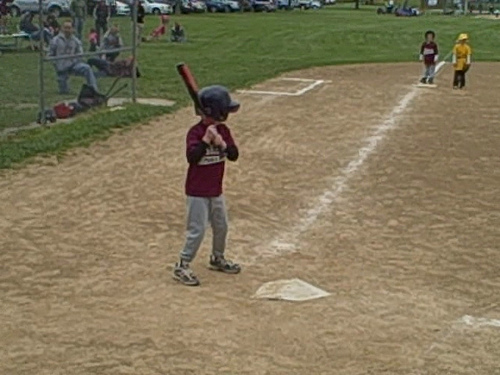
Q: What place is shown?
A: It is a field.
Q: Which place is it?
A: It is a field.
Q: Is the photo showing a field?
A: Yes, it is showing a field.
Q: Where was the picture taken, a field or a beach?
A: It was taken at a field.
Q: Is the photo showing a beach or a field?
A: It is showing a field.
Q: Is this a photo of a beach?
A: No, the picture is showing a field.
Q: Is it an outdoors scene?
A: Yes, it is outdoors.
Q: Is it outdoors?
A: Yes, it is outdoors.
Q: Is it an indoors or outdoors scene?
A: It is outdoors.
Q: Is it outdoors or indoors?
A: It is outdoors.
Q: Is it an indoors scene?
A: No, it is outdoors.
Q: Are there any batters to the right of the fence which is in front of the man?
A: Yes, there is a batter to the right of the fence.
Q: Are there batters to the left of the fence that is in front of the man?
A: No, the batter is to the right of the fence.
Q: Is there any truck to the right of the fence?
A: No, there is a batter to the right of the fence.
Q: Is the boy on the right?
A: Yes, the boy is on the right of the image.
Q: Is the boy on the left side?
A: No, the boy is on the right of the image.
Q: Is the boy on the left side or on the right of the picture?
A: The boy is on the right of the image.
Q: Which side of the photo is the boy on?
A: The boy is on the right of the image.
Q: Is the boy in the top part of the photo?
A: Yes, the boy is in the top of the image.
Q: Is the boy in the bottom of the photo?
A: No, the boy is in the top of the image.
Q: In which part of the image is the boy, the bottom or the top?
A: The boy is in the top of the image.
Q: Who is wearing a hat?
A: The boy is wearing a hat.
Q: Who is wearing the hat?
A: The boy is wearing a hat.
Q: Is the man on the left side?
A: Yes, the man is on the left of the image.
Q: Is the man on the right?
A: No, the man is on the left of the image.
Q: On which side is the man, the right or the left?
A: The man is on the left of the image.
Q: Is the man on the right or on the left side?
A: The man is on the left of the image.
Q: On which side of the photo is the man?
A: The man is on the left of the image.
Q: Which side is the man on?
A: The man is on the left of the image.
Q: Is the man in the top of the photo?
A: Yes, the man is in the top of the image.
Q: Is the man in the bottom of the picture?
A: No, the man is in the top of the image.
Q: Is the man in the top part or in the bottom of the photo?
A: The man is in the top of the image.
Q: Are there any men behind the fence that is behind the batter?
A: Yes, there is a man behind the fence.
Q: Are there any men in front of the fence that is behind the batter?
A: No, the man is behind the fence.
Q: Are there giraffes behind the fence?
A: No, there is a man behind the fence.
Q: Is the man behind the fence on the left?
A: Yes, the man is behind the fence.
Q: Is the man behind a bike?
A: No, the man is behind the fence.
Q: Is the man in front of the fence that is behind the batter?
A: No, the man is behind the fence.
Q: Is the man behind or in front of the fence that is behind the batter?
A: The man is behind the fence.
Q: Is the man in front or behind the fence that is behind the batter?
A: The man is behind the fence.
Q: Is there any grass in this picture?
A: Yes, there is grass.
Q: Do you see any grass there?
A: Yes, there is grass.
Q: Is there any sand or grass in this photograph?
A: Yes, there is grass.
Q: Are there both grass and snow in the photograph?
A: No, there is grass but no snow.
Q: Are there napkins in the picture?
A: No, there are no napkins.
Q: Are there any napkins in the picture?
A: No, there are no napkins.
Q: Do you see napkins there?
A: No, there are no napkins.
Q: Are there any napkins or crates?
A: No, there are no napkins or crates.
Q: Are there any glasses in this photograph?
A: No, there are no glasses.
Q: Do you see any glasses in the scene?
A: No, there are no glasses.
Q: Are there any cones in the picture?
A: No, there are no cones.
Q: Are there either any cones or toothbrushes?
A: No, there are no cones or toothbrushes.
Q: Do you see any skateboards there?
A: No, there are no skateboards.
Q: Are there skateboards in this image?
A: No, there are no skateboards.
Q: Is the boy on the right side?
A: Yes, the boy is on the right of the image.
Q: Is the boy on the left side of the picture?
A: No, the boy is on the right of the image.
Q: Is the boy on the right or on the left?
A: The boy is on the right of the image.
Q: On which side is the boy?
A: The boy is on the right of the image.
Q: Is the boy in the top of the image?
A: Yes, the boy is in the top of the image.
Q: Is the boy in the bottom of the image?
A: No, the boy is in the top of the image.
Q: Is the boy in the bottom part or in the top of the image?
A: The boy is in the top of the image.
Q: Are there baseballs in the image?
A: Yes, there is a baseball.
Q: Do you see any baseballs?
A: Yes, there is a baseball.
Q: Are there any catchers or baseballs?
A: Yes, there is a baseball.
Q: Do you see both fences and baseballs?
A: Yes, there are both a baseball and a fence.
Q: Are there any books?
A: No, there are no books.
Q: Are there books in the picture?
A: No, there are no books.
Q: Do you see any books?
A: No, there are no books.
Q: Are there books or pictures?
A: No, there are no books or pictures.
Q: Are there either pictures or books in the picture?
A: No, there are no books or pictures.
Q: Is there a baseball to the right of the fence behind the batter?
A: Yes, there is a baseball to the right of the fence.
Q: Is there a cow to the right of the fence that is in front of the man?
A: No, there is a baseball to the right of the fence.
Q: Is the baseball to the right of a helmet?
A: No, the baseball is to the right of the fence.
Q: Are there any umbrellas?
A: No, there are no umbrellas.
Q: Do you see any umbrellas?
A: No, there are no umbrellas.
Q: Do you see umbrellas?
A: No, there are no umbrellas.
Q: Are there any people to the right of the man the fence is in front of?
A: Yes, there are people to the right of the man.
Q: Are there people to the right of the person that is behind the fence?
A: Yes, there are people to the right of the man.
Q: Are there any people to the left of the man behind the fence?
A: No, the people are to the right of the man.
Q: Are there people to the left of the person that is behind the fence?
A: No, the people are to the right of the man.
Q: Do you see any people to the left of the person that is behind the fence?
A: No, the people are to the right of the man.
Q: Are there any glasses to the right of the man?
A: No, there are people to the right of the man.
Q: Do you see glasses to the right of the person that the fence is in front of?
A: No, there are people to the right of the man.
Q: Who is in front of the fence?
A: The batter is in front of the fence.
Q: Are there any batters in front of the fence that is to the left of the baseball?
A: Yes, there is a batter in front of the fence.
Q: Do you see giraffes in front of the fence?
A: No, there is a batter in front of the fence.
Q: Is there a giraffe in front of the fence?
A: No, there is a batter in front of the fence.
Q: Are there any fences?
A: Yes, there is a fence.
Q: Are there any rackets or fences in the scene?
A: Yes, there is a fence.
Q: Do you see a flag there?
A: No, there are no flags.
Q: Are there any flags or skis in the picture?
A: No, there are no flags or skis.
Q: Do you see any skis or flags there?
A: No, there are no flags or skis.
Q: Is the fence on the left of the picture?
A: Yes, the fence is on the left of the image.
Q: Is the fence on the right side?
A: No, the fence is on the left of the image.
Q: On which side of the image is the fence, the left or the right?
A: The fence is on the left of the image.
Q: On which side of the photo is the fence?
A: The fence is on the left of the image.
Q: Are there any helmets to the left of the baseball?
A: No, there is a fence to the left of the baseball.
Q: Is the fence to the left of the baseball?
A: Yes, the fence is to the left of the baseball.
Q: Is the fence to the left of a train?
A: No, the fence is to the left of the baseball.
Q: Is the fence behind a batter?
A: Yes, the fence is behind a batter.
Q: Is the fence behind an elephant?
A: No, the fence is behind a batter.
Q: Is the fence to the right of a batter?
A: No, the fence is to the left of a batter.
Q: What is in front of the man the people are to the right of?
A: The fence is in front of the man.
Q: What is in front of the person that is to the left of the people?
A: The fence is in front of the man.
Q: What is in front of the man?
A: The fence is in front of the man.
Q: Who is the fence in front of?
A: The fence is in front of the man.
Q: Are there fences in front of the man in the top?
A: Yes, there is a fence in front of the man.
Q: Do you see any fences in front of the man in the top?
A: Yes, there is a fence in front of the man.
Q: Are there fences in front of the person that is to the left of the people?
A: Yes, there is a fence in front of the man.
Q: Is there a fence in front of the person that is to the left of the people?
A: Yes, there is a fence in front of the man.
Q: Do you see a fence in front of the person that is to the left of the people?
A: Yes, there is a fence in front of the man.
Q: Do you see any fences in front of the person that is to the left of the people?
A: Yes, there is a fence in front of the man.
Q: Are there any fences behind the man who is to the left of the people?
A: No, the fence is in front of the man.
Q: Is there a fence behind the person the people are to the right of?
A: No, the fence is in front of the man.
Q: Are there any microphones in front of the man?
A: No, there is a fence in front of the man.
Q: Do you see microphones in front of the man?
A: No, there is a fence in front of the man.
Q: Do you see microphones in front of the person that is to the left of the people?
A: No, there is a fence in front of the man.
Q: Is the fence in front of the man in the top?
A: Yes, the fence is in front of the man.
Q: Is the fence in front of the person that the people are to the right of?
A: Yes, the fence is in front of the man.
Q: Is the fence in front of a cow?
A: No, the fence is in front of the man.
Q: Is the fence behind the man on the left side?
A: No, the fence is in front of the man.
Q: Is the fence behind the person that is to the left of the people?
A: No, the fence is in front of the man.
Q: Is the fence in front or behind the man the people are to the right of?
A: The fence is in front of the man.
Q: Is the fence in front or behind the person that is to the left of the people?
A: The fence is in front of the man.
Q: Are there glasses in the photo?
A: No, there are no glasses.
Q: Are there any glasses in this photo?
A: No, there are no glasses.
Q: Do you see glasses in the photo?
A: No, there are no glasses.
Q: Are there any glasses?
A: No, there are no glasses.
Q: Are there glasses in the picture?
A: No, there are no glasses.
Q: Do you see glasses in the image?
A: No, there are no glasses.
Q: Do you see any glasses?
A: No, there are no glasses.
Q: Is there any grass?
A: Yes, there is grass.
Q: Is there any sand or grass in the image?
A: Yes, there is grass.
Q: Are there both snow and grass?
A: No, there is grass but no snow.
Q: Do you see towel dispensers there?
A: No, there are no towel dispensers.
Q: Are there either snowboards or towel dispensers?
A: No, there are no towel dispensers or snowboards.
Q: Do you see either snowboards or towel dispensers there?
A: No, there are no towel dispensers or snowboards.